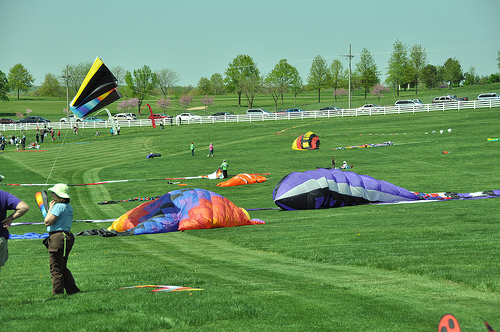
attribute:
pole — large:
[344, 39, 358, 119]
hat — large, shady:
[44, 180, 74, 198]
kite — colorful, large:
[74, 184, 264, 237]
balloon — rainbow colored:
[104, 190, 255, 237]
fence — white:
[8, 95, 481, 130]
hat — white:
[50, 181, 70, 198]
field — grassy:
[18, 126, 480, 330]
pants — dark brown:
[44, 224, 76, 328]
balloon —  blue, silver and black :
[318, 151, 340, 222]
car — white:
[241, 109, 271, 119]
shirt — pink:
[206, 145, 213, 148]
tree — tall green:
[14, 58, 32, 125]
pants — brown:
[46, 226, 83, 332]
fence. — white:
[232, 110, 401, 118]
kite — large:
[260, 136, 481, 255]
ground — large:
[264, 238, 384, 328]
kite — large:
[270, 109, 341, 173]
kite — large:
[200, 152, 269, 198]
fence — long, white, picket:
[165, 103, 302, 143]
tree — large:
[205, 45, 273, 119]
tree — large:
[228, 45, 301, 122]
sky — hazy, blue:
[127, 17, 218, 80]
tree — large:
[7, 41, 63, 115]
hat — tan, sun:
[35, 174, 80, 209]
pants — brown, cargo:
[30, 229, 101, 304]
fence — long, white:
[223, 77, 389, 133]